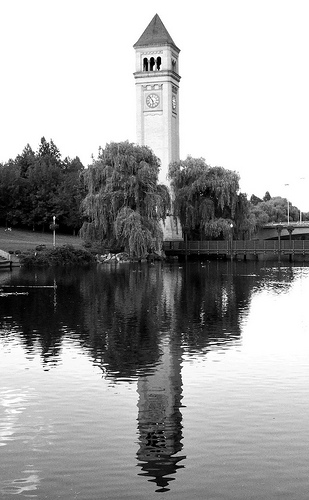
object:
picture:
[2, 2, 309, 500]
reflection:
[115, 317, 202, 496]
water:
[196, 331, 234, 398]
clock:
[144, 92, 162, 113]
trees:
[90, 138, 162, 248]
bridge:
[257, 217, 309, 242]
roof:
[128, 7, 183, 54]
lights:
[283, 198, 294, 212]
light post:
[43, 211, 67, 247]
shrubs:
[7, 186, 41, 230]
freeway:
[263, 221, 309, 229]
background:
[259, 182, 292, 196]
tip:
[148, 10, 164, 23]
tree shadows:
[198, 259, 261, 338]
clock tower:
[126, 6, 193, 242]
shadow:
[51, 299, 100, 346]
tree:
[185, 162, 245, 240]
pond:
[22, 423, 79, 500]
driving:
[293, 214, 303, 226]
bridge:
[172, 239, 308, 263]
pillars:
[147, 56, 152, 73]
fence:
[0, 251, 21, 271]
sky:
[220, 14, 302, 65]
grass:
[22, 231, 44, 241]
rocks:
[95, 251, 132, 267]